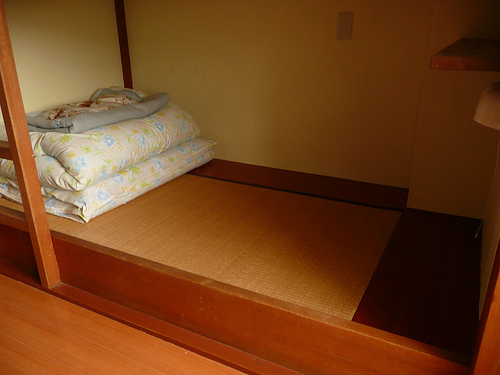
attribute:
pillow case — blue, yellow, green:
[25, 85, 168, 132]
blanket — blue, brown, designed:
[20, 85, 170, 132]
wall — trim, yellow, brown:
[122, 3, 492, 228]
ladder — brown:
[1, 10, 63, 291]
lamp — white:
[474, 81, 499, 131]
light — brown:
[472, 82, 497, 132]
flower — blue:
[96, 94, 135, 106]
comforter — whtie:
[2, 103, 217, 223]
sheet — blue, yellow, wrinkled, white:
[24, 85, 168, 137]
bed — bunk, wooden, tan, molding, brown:
[2, 158, 499, 371]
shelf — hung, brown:
[431, 37, 497, 74]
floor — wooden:
[2, 275, 250, 372]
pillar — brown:
[1, 7, 62, 291]